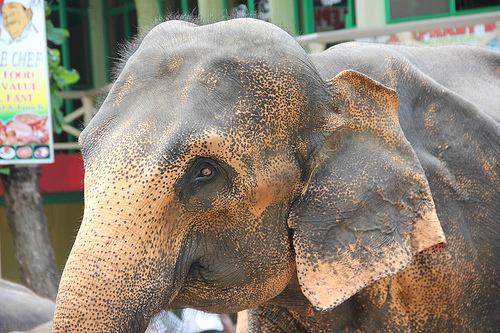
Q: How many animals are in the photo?
A: One.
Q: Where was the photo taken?
A: Outside on a street.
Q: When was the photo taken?
A: During the day.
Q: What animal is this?
A: Elephant.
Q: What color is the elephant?
A: Gray.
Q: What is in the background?
A: A building.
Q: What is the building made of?
A: Brick.